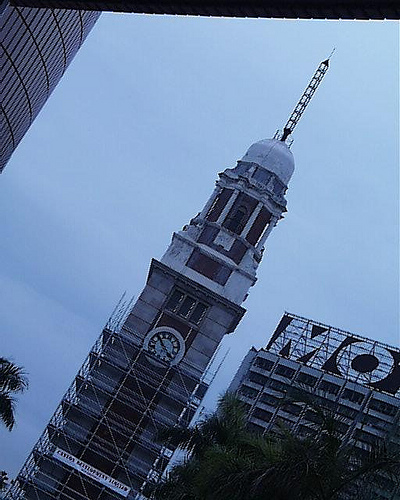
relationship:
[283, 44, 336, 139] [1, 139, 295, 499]
tip of building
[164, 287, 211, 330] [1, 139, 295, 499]
windows on building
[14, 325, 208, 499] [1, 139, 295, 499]
stairs up tower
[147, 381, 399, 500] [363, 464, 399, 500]
tree in corner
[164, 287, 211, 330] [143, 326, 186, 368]
windows above clock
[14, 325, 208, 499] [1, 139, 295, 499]
scaffolding on building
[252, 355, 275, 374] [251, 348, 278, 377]
window in corner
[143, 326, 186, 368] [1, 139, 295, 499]
clock on tower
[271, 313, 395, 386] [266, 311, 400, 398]
mo on billboard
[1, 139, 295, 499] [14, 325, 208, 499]
clocktower with scaffolding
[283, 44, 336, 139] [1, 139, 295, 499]
spire of tower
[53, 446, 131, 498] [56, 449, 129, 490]
banner with letters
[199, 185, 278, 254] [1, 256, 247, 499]
pillars above clocktower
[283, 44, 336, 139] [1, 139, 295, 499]
spire on tower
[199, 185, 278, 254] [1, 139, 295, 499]
columns on tower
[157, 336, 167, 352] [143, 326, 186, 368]
hand on clock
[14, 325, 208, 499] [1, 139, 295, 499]
scaffolding around tower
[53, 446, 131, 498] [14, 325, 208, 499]
banner on scaffolding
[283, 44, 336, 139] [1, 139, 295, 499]
tip on tower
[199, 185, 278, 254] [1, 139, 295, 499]
pillars on tower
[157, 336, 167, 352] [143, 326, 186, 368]
hand of clock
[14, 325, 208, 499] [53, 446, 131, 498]
scaffolding by sign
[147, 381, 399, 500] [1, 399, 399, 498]
palm in foreground